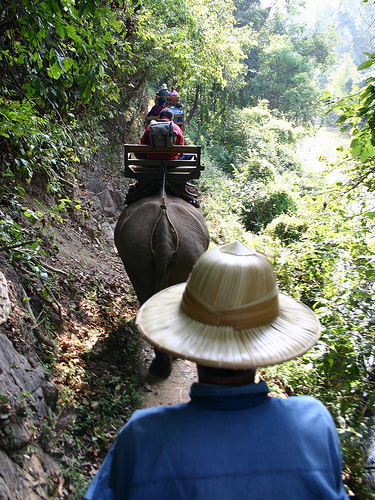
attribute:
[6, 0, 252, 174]
foliage — green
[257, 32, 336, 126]
trees — green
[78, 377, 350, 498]
shirt — blue